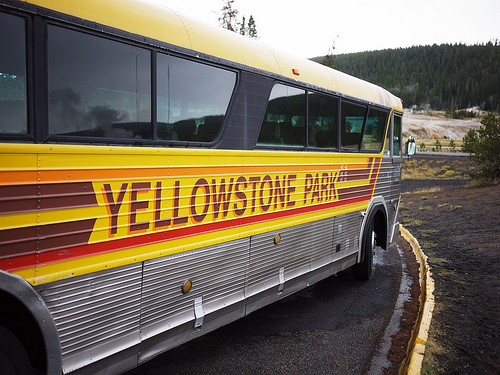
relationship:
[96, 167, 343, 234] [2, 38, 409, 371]
lettering on bus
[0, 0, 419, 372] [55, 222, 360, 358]
bus has siding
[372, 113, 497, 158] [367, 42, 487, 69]
mountain covered covered trees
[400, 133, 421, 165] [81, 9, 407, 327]
mirror on bus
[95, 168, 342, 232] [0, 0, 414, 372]
sign on bus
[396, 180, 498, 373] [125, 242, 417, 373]
dirt on side of road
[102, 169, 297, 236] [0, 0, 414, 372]
word on bus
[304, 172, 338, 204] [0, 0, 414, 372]
park. on bus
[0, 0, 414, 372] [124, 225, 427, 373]
bus on road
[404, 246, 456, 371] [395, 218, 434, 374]
curb on border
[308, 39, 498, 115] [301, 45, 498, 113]
trees on a mountain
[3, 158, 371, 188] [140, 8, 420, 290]
orange stripe on bus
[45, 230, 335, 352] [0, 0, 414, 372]
silver area on bus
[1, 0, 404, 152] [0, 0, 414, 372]
windows along side of bus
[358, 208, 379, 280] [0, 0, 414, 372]
wheel on bus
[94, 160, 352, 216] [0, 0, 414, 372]
writing on bus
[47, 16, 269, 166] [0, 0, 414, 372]
window on bus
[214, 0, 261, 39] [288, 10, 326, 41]
trees in sky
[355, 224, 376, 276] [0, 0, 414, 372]
black tire on front bus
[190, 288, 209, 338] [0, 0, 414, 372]
latch on bus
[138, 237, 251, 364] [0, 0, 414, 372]
door on bus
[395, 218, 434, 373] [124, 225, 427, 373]
border on road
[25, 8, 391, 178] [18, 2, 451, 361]
windows on bus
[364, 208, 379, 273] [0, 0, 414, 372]
wheel of bus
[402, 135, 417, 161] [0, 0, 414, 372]
mirror of bus